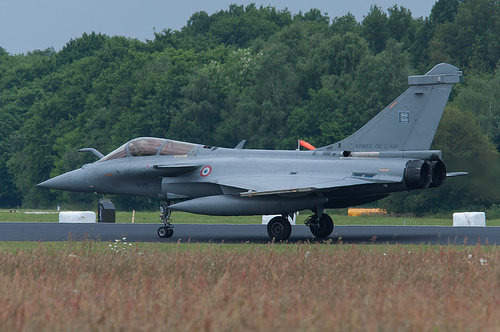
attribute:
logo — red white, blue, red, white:
[200, 164, 213, 177]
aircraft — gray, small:
[34, 61, 469, 241]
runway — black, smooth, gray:
[0, 222, 499, 247]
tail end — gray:
[319, 59, 471, 194]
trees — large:
[0, 1, 499, 219]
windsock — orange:
[295, 137, 318, 152]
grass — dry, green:
[1, 208, 499, 230]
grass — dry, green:
[0, 243, 498, 331]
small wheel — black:
[155, 220, 175, 240]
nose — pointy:
[36, 151, 107, 198]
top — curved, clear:
[93, 134, 210, 163]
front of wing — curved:
[160, 177, 258, 199]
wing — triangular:
[163, 170, 399, 200]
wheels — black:
[308, 212, 337, 240]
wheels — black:
[266, 215, 294, 241]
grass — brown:
[2, 255, 496, 331]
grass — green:
[1, 240, 498, 254]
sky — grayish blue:
[0, 1, 440, 58]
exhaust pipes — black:
[405, 157, 450, 191]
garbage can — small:
[95, 197, 118, 225]